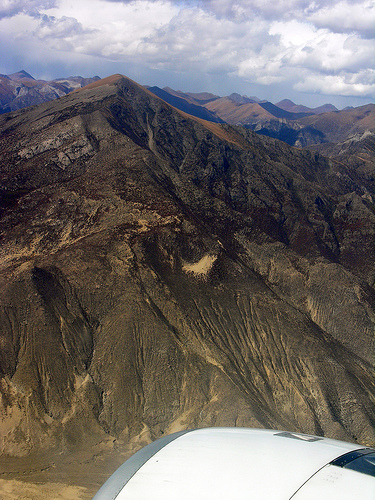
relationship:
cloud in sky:
[0, 1, 68, 12] [7, 71, 371, 95]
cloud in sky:
[0, 0, 375, 93] [7, 71, 371, 95]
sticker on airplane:
[271, 427, 327, 446] [88, 424, 374, 498]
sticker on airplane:
[271, 427, 327, 446] [85, 410, 366, 496]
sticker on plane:
[271, 427, 327, 446] [107, 425, 367, 495]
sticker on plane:
[271, 427, 327, 446] [95, 413, 353, 498]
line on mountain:
[219, 342, 269, 376] [52, 85, 249, 248]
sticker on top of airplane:
[271, 427, 327, 446] [88, 424, 374, 498]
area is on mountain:
[178, 248, 219, 275] [0, 73, 371, 466]